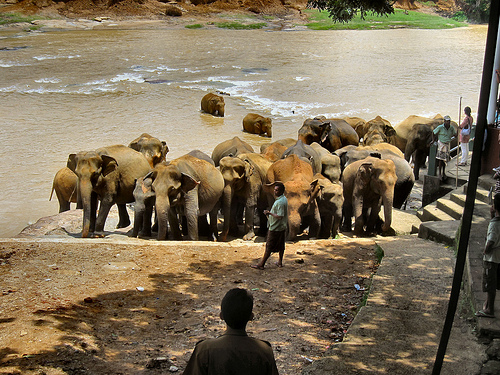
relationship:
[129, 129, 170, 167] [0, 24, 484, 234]
elephant leaving river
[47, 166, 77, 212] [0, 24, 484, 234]
elephant leaving river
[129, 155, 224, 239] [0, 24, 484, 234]
elephant leaving river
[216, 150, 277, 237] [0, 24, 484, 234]
elephant leaving river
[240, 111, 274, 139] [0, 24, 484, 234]
elephant leaving river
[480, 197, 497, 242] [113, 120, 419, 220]
man looking at elephants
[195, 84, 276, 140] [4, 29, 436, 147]
elephants in river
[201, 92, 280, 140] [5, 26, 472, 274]
elephants in river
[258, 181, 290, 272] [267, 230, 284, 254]
guy wearing shorts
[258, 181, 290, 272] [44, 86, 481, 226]
guy in front of elephants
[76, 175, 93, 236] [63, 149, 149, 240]
trunk of elephant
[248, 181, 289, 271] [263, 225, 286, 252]
guy wearing shorts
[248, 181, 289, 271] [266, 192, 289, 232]
guy wearing polo shirt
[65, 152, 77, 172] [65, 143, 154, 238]
ear belonging to elephant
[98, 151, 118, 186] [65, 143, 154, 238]
ear belonging to elephant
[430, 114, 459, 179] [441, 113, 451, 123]
guy wearing hat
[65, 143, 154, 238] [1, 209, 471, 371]
elephant walking up river bank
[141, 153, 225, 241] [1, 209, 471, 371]
elephant walking up river bank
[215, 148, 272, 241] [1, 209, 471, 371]
elephant walking up river bank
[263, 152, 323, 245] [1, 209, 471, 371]
elephant walking up river bank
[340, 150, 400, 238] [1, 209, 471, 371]
elephant walking up river bank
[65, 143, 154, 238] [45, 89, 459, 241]
elephant walking in group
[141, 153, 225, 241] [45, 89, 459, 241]
elephant walking in group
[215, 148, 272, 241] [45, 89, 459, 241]
elephant walking in group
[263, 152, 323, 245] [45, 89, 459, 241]
elephant walking in group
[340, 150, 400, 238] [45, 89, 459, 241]
elephant walking in group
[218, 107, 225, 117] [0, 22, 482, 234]
trunk placed in water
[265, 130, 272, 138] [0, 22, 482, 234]
trunk placed in water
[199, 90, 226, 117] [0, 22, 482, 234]
elephant walking in water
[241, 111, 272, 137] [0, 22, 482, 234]
elephant walking in water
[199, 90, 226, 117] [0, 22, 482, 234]
elephant half way submerged in water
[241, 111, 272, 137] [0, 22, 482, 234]
elephant half way submerged in water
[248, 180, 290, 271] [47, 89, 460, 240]
man standing in front of herd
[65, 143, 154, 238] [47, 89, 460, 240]
elephant walking in herd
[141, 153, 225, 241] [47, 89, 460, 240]
elephant walking in herd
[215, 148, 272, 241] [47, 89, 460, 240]
elephant walking in herd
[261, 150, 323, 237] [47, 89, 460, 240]
elephant walking in herd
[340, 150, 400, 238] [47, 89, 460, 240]
elephant walking in herd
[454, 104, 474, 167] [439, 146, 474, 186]
woman standing on dock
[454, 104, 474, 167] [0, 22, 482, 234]
woman standing in front of water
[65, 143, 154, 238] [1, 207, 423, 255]
elephant walking up water's edge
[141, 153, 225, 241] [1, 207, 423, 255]
elephant walking up water's edge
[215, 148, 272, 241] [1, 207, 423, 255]
elephant walking up water's edge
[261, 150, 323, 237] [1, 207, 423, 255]
elephant walking up water's edge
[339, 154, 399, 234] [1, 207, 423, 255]
elephant walking up water's edge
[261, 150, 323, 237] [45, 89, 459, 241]
elephant walking in group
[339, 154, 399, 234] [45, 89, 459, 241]
elephant walking in group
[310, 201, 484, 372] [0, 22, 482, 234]
walkway leading to water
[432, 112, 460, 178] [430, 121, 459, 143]
man wearing shirt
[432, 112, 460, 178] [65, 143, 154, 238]
man facing away from elephant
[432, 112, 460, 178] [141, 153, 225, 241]
man facing away from elephant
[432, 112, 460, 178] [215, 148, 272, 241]
man facing away from elephant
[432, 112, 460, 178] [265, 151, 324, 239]
man facing away from elephant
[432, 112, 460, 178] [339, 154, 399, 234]
man facing away from elephant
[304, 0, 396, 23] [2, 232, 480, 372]
tree casting shadow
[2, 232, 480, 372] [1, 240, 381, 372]
shadow casted on beach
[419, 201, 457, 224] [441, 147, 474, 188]
step leading to dock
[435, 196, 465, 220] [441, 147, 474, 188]
step leading to dock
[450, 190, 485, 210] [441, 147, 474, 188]
step leading to dock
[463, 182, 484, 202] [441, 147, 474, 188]
step leading to dock